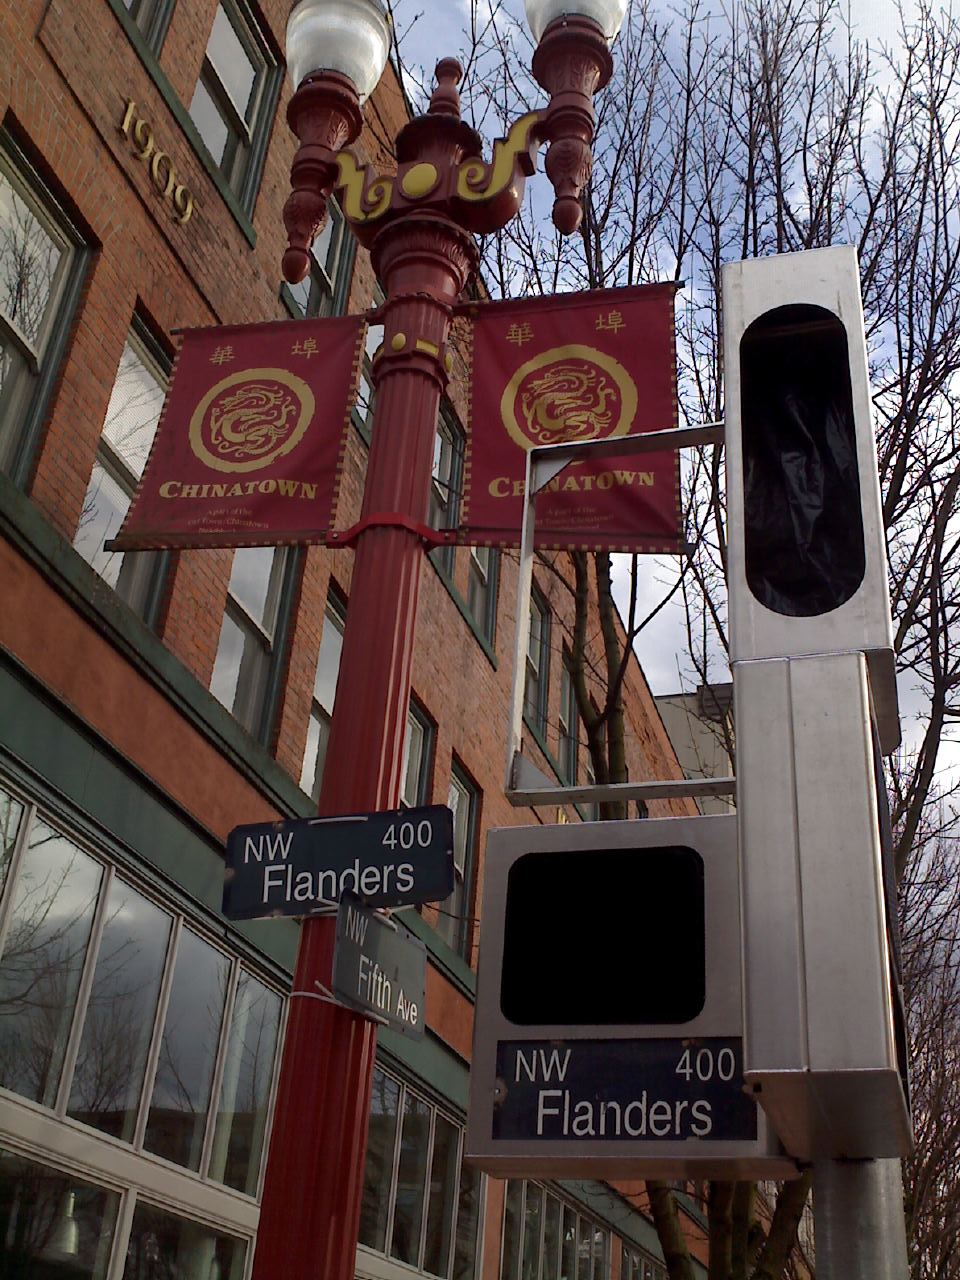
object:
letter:
[538, 1090, 562, 1134]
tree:
[384, 0, 959, 1280]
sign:
[492, 1038, 758, 1142]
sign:
[332, 887, 429, 1044]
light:
[536, 6, 626, 30]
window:
[69, 293, 306, 760]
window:
[72, 437, 168, 626]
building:
[1, 0, 814, 1280]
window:
[206, 587, 279, 750]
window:
[226, 534, 302, 644]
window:
[297, 695, 336, 795]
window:
[400, 687, 439, 809]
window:
[467, 553, 499, 652]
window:
[61, 860, 319, 1203]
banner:
[460, 281, 684, 555]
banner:
[113, 314, 367, 549]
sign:
[222, 805, 452, 922]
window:
[136, 916, 234, 1173]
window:
[296, 567, 439, 912]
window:
[354, 1043, 487, 1276]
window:
[499, 1175, 612, 1280]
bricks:
[430, 625, 468, 692]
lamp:
[738, 300, 867, 620]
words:
[513, 1045, 736, 1137]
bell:
[52, 1197, 80, 1255]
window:
[0, 1140, 124, 1280]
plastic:
[721, 243, 902, 753]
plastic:
[463, 810, 796, 1183]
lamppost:
[241, 50, 481, 1280]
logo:
[502, 344, 639, 464]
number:
[122, 97, 194, 225]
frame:
[504, 420, 735, 805]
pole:
[813, 1113, 898, 1280]